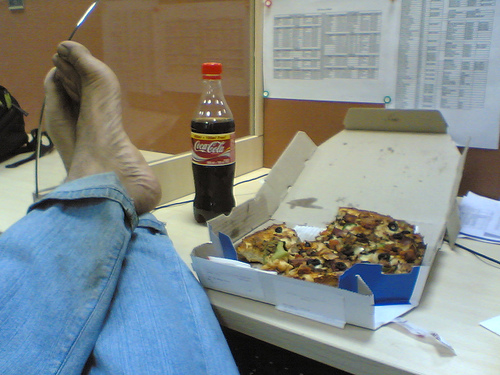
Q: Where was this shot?
A: Office.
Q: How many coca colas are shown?
A: 1.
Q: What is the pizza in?
A: Cardboard.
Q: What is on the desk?
A: Bare feet.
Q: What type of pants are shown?
A: Jeans.